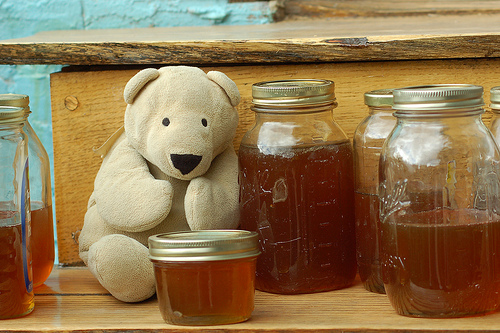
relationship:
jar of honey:
[144, 221, 271, 327] [166, 270, 244, 305]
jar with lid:
[144, 221, 271, 327] [144, 227, 262, 258]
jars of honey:
[222, 66, 499, 322] [166, 270, 244, 305]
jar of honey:
[375, 82, 498, 319] [408, 234, 492, 279]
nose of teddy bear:
[168, 150, 202, 177] [70, 60, 247, 306]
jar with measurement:
[236, 76, 360, 292] [307, 211, 347, 276]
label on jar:
[16, 154, 35, 299] [1, 103, 38, 323]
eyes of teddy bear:
[158, 115, 214, 129] [70, 60, 247, 306]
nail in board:
[60, 93, 83, 113] [47, 60, 498, 268]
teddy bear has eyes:
[70, 60, 247, 306] [158, 115, 214, 129]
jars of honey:
[222, 66, 499, 322] [408, 234, 492, 279]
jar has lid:
[144, 221, 271, 327] [144, 227, 262, 258]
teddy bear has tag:
[70, 60, 247, 306] [90, 125, 124, 157]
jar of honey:
[236, 76, 360, 292] [166, 270, 244, 305]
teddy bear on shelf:
[70, 60, 247, 306] [2, 265, 499, 333]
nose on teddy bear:
[168, 150, 202, 177] [70, 60, 247, 306]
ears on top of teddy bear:
[121, 66, 245, 107] [70, 60, 247, 306]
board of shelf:
[47, 60, 498, 268] [2, 265, 499, 333]